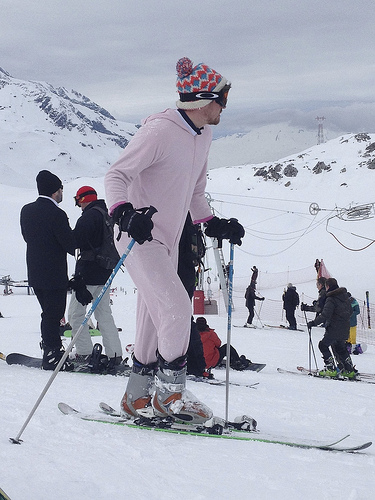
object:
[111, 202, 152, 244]
gloves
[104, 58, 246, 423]
man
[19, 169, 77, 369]
man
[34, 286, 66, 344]
pants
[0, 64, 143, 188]
mountain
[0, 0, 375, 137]
sky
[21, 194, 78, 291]
outfit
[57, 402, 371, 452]
skis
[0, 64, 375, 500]
snow